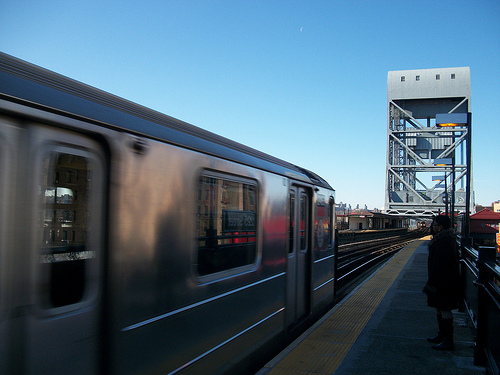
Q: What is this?
A: Train.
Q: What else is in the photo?
A: Train tracks.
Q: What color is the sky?
A: Blue.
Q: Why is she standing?
A: Waiting.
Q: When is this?
A: Daytime.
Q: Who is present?
A: Woman.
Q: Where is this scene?
A: At a train stop.